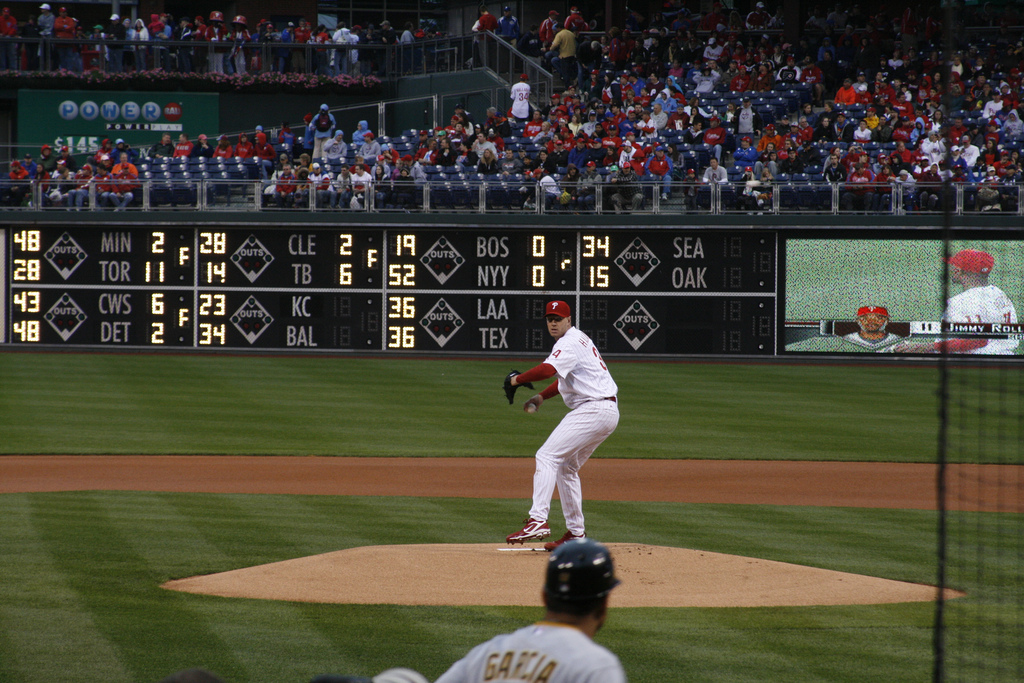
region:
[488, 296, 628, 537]
the pitcher on the mound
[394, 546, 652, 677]
batter on the field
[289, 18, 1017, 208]
fans in the crowd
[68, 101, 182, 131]
lottery power ball sign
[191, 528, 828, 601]
the baseball pitcher's mound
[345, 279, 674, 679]
two opposing baseball players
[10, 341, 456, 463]
the outfield of baseball stadium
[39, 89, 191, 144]
lottery advertisement on the wall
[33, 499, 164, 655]
green grass of the infield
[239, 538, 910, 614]
pitcher's mound in the infield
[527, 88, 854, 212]
fans sitting in the stands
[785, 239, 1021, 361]
television screen against the back wall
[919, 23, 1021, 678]
black net behind home plate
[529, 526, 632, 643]
Player wearing a black helmet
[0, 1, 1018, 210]
Spectators watching a game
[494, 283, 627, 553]
Pitcher is wearing a white uniform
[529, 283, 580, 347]
A red hat on pitcher's head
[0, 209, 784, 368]
A scoreboard with lit up numbers on it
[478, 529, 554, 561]
A white pitcher's mound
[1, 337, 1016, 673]
Green grass on the baseball field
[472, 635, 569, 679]
"GARCIA" on back of shirt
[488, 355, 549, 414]
A black leather baseball glove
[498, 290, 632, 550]
pitcher on the mound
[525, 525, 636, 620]
black batting helmet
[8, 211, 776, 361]
scoreboard on the fence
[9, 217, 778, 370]
scoreboard behind the pitcher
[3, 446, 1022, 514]
basepath behind the pitcher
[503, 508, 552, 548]
foot off the mound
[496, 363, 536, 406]
black glove on the pitcher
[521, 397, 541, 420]
ball in the right hand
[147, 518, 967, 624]
mound in the infield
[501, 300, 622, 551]
pitcher standing on mound in stadium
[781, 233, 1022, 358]
big screen television monitor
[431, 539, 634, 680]
baseball player with Garcia on jersey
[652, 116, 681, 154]
a person watching the game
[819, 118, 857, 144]
a person watching the game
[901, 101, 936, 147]
a person watching the game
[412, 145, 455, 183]
a person watching the game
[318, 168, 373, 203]
a person watching the game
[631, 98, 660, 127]
a person watching the game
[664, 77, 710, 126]
a person watching the game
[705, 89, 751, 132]
a person watching the game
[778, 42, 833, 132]
a person watching the game